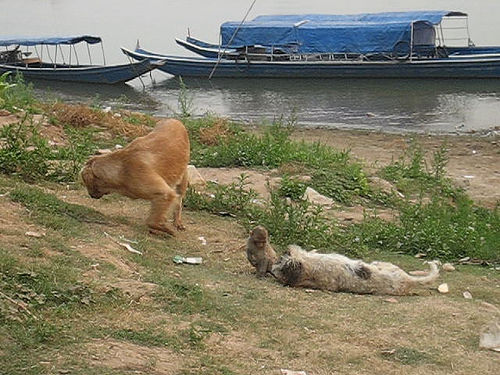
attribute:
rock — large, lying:
[363, 170, 399, 204]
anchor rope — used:
[208, 1, 258, 80]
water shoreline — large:
[164, 111, 496, 139]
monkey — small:
[257, 117, 470, 317]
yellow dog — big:
[77, 105, 206, 248]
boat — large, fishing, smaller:
[7, 33, 158, 87]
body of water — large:
[43, 63, 498, 143]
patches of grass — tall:
[31, 89, 296, 162]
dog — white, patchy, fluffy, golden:
[88, 112, 205, 253]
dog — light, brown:
[70, 120, 202, 240]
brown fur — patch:
[75, 108, 205, 232]